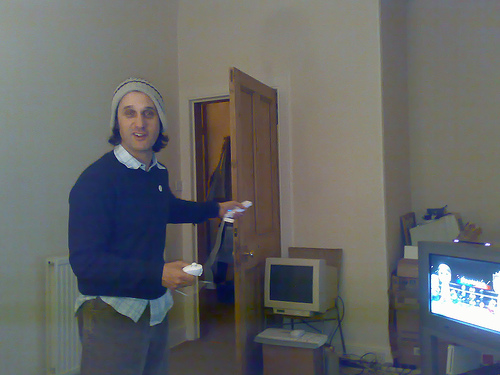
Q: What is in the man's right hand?
A: Game controller.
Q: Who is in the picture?
A: A man.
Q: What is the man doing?
A: Playing a video game.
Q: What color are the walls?
A: White.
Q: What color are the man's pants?
A: Brown.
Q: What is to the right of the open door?
A: A computer.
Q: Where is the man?
A: In a room.